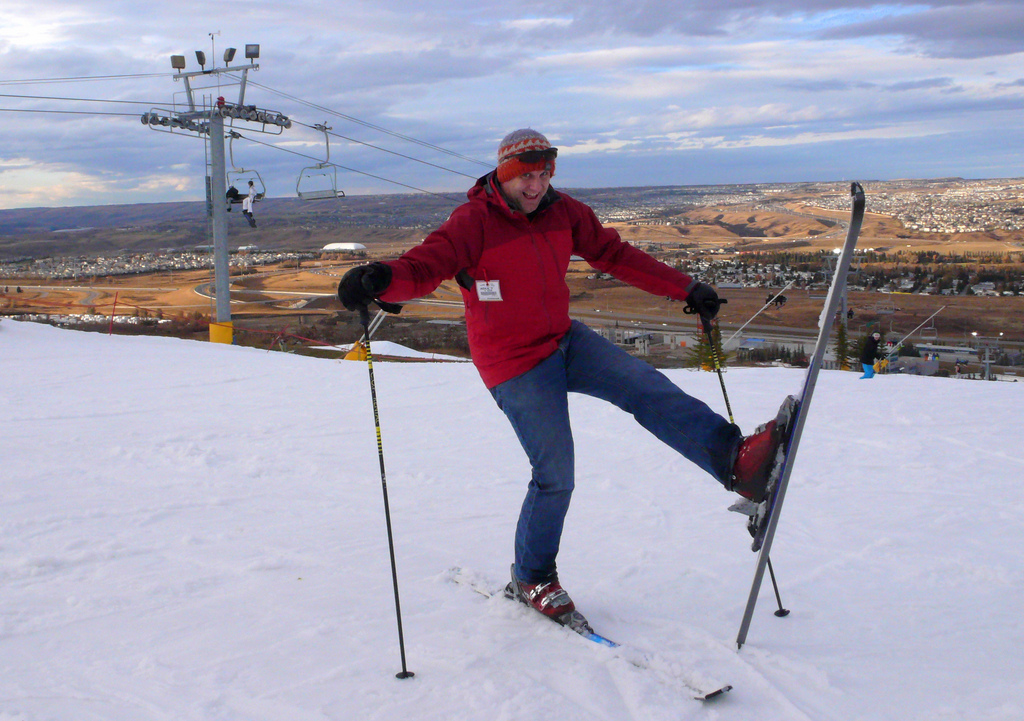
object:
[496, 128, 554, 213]
head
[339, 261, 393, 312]
glove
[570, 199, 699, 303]
arm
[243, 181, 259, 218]
person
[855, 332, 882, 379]
person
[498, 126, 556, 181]
ski cap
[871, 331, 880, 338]
ski cap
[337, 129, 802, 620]
man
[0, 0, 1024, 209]
clouds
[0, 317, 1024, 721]
snow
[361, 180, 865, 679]
foot prints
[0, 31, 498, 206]
cables